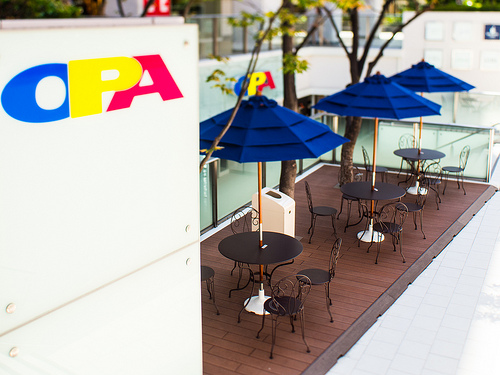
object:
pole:
[258, 162, 263, 249]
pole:
[369, 120, 380, 190]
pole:
[419, 93, 421, 149]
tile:
[431, 339, 465, 358]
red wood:
[341, 267, 376, 300]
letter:
[104, 51, 183, 114]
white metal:
[252, 187, 296, 242]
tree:
[337, 58, 384, 183]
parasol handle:
[257, 162, 264, 250]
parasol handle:
[373, 116, 378, 185]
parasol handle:
[419, 92, 423, 151]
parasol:
[198, 93, 348, 165]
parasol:
[309, 71, 442, 121]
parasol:
[388, 58, 480, 92]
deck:
[220, 225, 305, 301]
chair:
[253, 273, 313, 358]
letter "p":
[67, 54, 142, 116]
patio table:
[303, 154, 435, 281]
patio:
[198, 84, 500, 374]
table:
[215, 220, 299, 320]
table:
[390, 143, 439, 197]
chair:
[294, 238, 343, 327]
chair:
[226, 207, 271, 283]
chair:
[303, 178, 343, 244]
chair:
[359, 193, 415, 274]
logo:
[9, 48, 225, 156]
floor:
[203, 301, 376, 374]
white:
[262, 206, 281, 231]